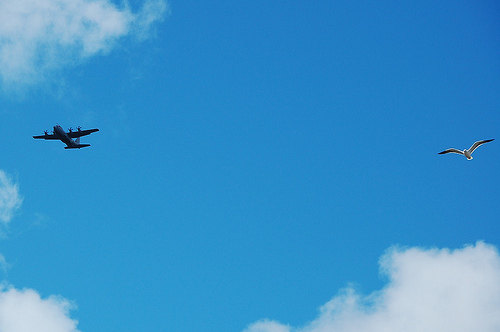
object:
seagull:
[437, 138, 496, 161]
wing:
[437, 148, 464, 155]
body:
[463, 151, 472, 159]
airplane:
[32, 123, 100, 149]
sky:
[0, 0, 496, 330]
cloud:
[243, 238, 500, 331]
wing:
[67, 128, 99, 139]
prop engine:
[68, 127, 74, 133]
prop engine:
[75, 126, 82, 132]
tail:
[63, 137, 91, 149]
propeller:
[68, 127, 73, 131]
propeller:
[76, 125, 83, 128]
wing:
[31, 135, 59, 141]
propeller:
[41, 130, 49, 134]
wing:
[79, 144, 91, 148]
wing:
[64, 146, 74, 149]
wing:
[469, 139, 495, 155]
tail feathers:
[467, 158, 468, 160]